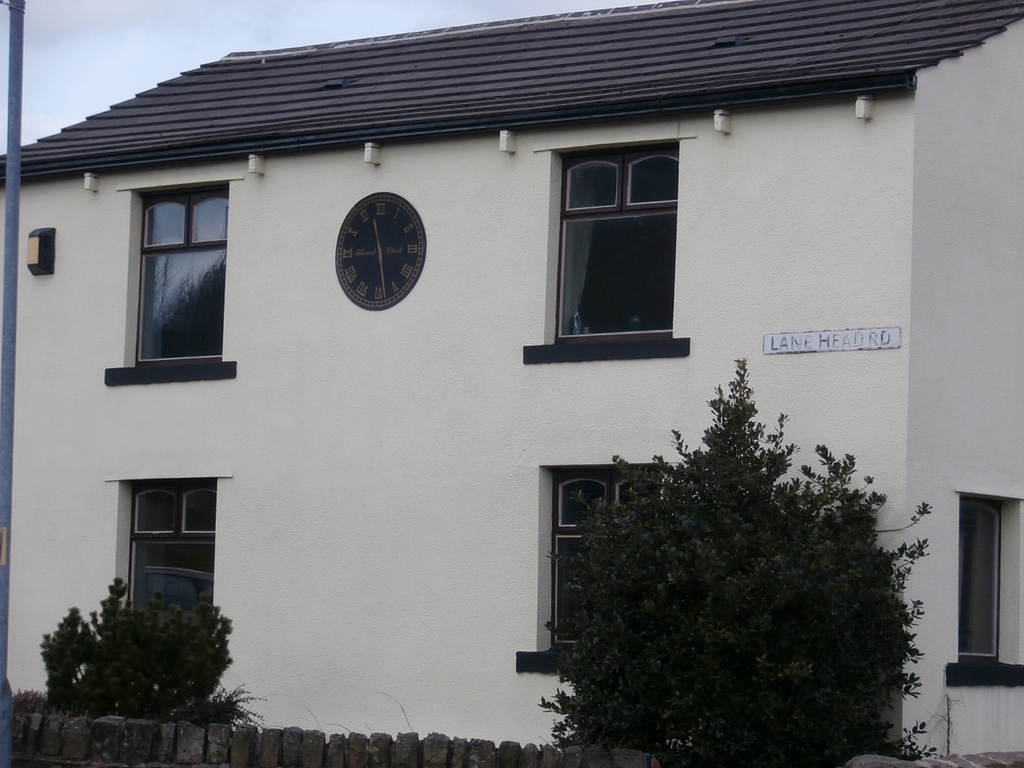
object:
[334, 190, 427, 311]
clock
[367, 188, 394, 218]
numeral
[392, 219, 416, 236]
numeral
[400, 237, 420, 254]
numeral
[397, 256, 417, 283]
numeral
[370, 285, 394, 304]
numeral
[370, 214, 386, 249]
hand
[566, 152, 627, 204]
plate glass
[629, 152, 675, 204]
plate glass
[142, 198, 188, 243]
plate glass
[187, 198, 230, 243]
plate glass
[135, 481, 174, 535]
plate glass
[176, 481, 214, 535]
plate glass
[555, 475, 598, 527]
plate glass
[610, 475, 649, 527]
plate glass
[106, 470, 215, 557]
window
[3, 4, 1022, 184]
roof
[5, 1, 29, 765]
pole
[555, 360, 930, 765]
bush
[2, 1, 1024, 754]
building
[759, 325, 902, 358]
letters